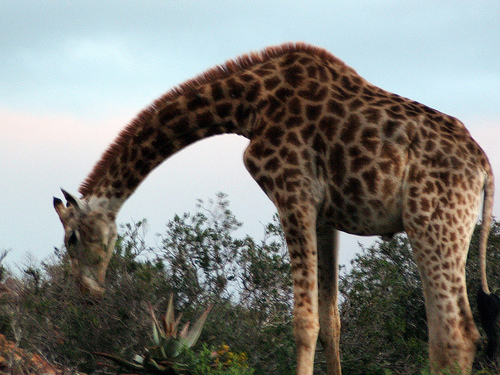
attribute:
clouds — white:
[0, 77, 96, 164]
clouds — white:
[390, 15, 498, 118]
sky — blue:
[33, 14, 428, 172]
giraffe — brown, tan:
[94, 55, 478, 365]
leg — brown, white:
[270, 210, 332, 372]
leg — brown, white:
[312, 226, 349, 373]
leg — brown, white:
[398, 216, 486, 373]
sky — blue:
[3, 5, 495, 182]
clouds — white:
[10, 81, 284, 205]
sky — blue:
[368, 33, 439, 77]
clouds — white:
[23, 103, 74, 133]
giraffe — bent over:
[3, 71, 471, 351]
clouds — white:
[369, 7, 449, 52]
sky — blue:
[0, 0, 498, 307]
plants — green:
[33, 240, 282, 370]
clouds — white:
[23, 32, 120, 131]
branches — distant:
[9, 221, 309, 373]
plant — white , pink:
[103, 293, 224, 373]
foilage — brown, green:
[125, 221, 286, 328]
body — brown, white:
[232, 51, 496, 309]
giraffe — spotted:
[55, 41, 494, 373]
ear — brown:
[60, 187, 87, 214]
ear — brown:
[52, 197, 71, 222]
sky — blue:
[57, 9, 197, 59]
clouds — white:
[0, 0, 498, 301]